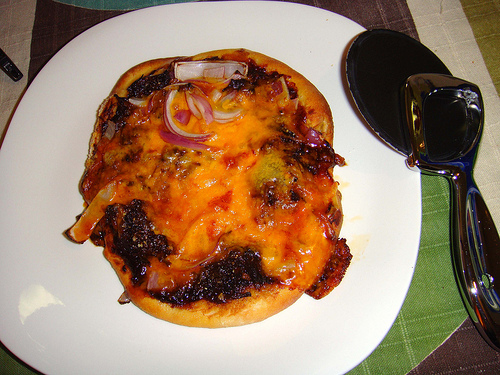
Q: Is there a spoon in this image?
A: Yes, there is a spoon.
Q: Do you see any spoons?
A: Yes, there is a spoon.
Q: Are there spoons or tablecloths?
A: Yes, there is a spoon.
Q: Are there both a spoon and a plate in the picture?
A: Yes, there are both a spoon and a plate.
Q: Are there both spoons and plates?
A: Yes, there are both a spoon and a plate.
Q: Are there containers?
A: No, there are no containers.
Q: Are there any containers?
A: No, there are no containers.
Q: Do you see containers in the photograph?
A: No, there are no containers.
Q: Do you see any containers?
A: No, there are no containers.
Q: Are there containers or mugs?
A: No, there are no containers or mugs.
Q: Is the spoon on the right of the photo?
A: Yes, the spoon is on the right of the image.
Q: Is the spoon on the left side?
A: No, the spoon is on the right of the image.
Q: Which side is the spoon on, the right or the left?
A: The spoon is on the right of the image.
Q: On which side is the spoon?
A: The spoon is on the right of the image.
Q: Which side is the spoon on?
A: The spoon is on the right of the image.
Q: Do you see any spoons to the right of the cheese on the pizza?
A: Yes, there is a spoon to the right of the cheese.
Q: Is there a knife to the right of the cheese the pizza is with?
A: No, there is a spoon to the right of the cheese.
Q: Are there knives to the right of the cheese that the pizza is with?
A: No, there is a spoon to the right of the cheese.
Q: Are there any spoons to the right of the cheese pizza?
A: Yes, there is a spoon to the right of the pizza.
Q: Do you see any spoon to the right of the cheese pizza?
A: Yes, there is a spoon to the right of the pizza.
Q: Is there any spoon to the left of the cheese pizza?
A: No, the spoon is to the right of the pizza.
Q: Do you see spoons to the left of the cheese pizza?
A: No, the spoon is to the right of the pizza.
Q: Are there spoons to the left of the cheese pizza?
A: No, the spoon is to the right of the pizza.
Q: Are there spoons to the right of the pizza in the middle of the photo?
A: Yes, there is a spoon to the right of the pizza.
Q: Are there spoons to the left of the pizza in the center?
A: No, the spoon is to the right of the pizza.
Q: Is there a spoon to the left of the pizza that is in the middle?
A: No, the spoon is to the right of the pizza.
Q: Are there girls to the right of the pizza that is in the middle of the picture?
A: No, there is a spoon to the right of the pizza.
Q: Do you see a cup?
A: No, there are no cups.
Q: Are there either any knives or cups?
A: No, there are no cups or knives.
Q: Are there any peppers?
A: No, there are no peppers.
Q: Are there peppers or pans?
A: No, there are no peppers or pans.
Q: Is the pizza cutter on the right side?
A: Yes, the pizza cutter is on the right of the image.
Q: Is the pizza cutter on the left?
A: No, the pizza cutter is on the right of the image.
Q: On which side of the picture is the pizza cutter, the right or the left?
A: The pizza cutter is on the right of the image.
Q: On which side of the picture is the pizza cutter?
A: The pizza cutter is on the right of the image.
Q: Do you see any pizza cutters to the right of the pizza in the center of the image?
A: Yes, there is a pizza cutter to the right of the pizza.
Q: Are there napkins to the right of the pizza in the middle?
A: No, there is a pizza cutter to the right of the pizza.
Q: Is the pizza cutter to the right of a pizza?
A: Yes, the pizza cutter is to the right of a pizza.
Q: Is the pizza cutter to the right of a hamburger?
A: No, the pizza cutter is to the right of a pizza.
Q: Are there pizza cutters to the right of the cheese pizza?
A: Yes, there is a pizza cutter to the right of the pizza.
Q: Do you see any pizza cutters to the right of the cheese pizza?
A: Yes, there is a pizza cutter to the right of the pizza.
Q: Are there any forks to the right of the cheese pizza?
A: No, there is a pizza cutter to the right of the pizza.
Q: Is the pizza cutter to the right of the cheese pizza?
A: Yes, the pizza cutter is to the right of the pizza.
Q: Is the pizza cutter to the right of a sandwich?
A: No, the pizza cutter is to the right of the pizza.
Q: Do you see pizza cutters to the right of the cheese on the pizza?
A: Yes, there is a pizza cutter to the right of the cheese.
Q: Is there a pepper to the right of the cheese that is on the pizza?
A: No, there is a pizza cutter to the right of the cheese.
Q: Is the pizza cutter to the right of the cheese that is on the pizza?
A: Yes, the pizza cutter is to the right of the cheese.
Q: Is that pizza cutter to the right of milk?
A: No, the pizza cutter is to the right of the cheese.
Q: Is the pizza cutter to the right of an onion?
A: Yes, the pizza cutter is to the right of an onion.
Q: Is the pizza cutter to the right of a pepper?
A: No, the pizza cutter is to the right of an onion.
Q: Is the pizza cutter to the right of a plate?
A: Yes, the pizza cutter is to the right of a plate.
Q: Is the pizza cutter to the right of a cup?
A: No, the pizza cutter is to the right of a plate.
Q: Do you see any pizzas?
A: Yes, there is a pizza.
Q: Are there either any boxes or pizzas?
A: Yes, there is a pizza.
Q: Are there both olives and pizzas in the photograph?
A: No, there is a pizza but no olives.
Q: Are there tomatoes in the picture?
A: No, there are no tomatoes.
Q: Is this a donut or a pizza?
A: This is a pizza.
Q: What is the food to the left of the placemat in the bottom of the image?
A: The food is a pizza.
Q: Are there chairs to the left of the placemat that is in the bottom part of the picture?
A: No, there is a pizza to the left of the placemat.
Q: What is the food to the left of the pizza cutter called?
A: The food is a pizza.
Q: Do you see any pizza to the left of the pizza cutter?
A: Yes, there is a pizza to the left of the pizza cutter.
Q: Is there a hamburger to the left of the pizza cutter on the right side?
A: No, there is a pizza to the left of the pizza cutter.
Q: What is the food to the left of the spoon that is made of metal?
A: The food is a pizza.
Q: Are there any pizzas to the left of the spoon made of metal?
A: Yes, there is a pizza to the left of the spoon.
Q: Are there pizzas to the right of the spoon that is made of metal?
A: No, the pizza is to the left of the spoon.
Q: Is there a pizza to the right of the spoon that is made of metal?
A: No, the pizza is to the left of the spoon.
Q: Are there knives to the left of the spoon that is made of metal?
A: No, there is a pizza to the left of the spoon.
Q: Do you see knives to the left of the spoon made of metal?
A: No, there is a pizza to the left of the spoon.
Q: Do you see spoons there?
A: Yes, there is a spoon.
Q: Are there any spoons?
A: Yes, there is a spoon.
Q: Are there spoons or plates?
A: Yes, there is a spoon.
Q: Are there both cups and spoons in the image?
A: No, there is a spoon but no cups.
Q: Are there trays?
A: No, there are no trays.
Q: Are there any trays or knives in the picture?
A: No, there are no trays or knives.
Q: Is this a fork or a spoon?
A: This is a spoon.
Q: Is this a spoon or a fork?
A: This is a spoon.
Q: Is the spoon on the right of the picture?
A: Yes, the spoon is on the right of the image.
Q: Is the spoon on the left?
A: No, the spoon is on the right of the image.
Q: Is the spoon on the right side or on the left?
A: The spoon is on the right of the image.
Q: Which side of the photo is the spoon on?
A: The spoon is on the right of the image.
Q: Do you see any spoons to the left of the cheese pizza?
A: No, the spoon is to the right of the pizza.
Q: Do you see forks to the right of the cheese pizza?
A: No, there is a spoon to the right of the pizza.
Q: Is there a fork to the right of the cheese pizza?
A: No, there is a spoon to the right of the pizza.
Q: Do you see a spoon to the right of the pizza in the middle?
A: Yes, there is a spoon to the right of the pizza.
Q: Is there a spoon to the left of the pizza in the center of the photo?
A: No, the spoon is to the right of the pizza.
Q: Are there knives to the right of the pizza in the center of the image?
A: No, there is a spoon to the right of the pizza.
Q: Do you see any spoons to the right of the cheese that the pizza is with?
A: Yes, there is a spoon to the right of the cheese.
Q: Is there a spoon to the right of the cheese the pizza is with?
A: Yes, there is a spoon to the right of the cheese.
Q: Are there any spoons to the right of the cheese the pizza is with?
A: Yes, there is a spoon to the right of the cheese.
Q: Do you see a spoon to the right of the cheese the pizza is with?
A: Yes, there is a spoon to the right of the cheese.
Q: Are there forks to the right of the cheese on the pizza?
A: No, there is a spoon to the right of the cheese.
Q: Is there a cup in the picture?
A: No, there are no cups.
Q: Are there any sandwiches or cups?
A: No, there are no cups or sandwiches.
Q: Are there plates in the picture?
A: Yes, there is a plate.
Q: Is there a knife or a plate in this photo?
A: Yes, there is a plate.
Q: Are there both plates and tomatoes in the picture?
A: No, there is a plate but no tomatoes.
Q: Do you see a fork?
A: No, there are no forks.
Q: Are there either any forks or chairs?
A: No, there are no forks or chairs.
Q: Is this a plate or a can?
A: This is a plate.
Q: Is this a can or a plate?
A: This is a plate.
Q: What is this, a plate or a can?
A: This is a plate.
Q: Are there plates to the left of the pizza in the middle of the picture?
A: Yes, there is a plate to the left of the pizza.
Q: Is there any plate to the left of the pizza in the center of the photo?
A: Yes, there is a plate to the left of the pizza.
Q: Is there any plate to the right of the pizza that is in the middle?
A: No, the plate is to the left of the pizza.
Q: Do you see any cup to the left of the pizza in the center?
A: No, there is a plate to the left of the pizza.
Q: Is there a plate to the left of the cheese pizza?
A: Yes, there is a plate to the left of the pizza.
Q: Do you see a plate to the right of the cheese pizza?
A: No, the plate is to the left of the pizza.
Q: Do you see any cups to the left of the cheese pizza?
A: No, there is a plate to the left of the pizza.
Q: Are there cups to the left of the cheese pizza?
A: No, there is a plate to the left of the pizza.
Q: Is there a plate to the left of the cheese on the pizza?
A: Yes, there is a plate to the left of the cheese.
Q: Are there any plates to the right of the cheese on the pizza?
A: No, the plate is to the left of the cheese.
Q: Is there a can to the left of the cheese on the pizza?
A: No, there is a plate to the left of the cheese.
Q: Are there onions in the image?
A: Yes, there is an onion.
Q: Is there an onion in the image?
A: Yes, there is an onion.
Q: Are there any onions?
A: Yes, there is an onion.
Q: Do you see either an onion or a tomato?
A: Yes, there is an onion.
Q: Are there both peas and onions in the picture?
A: No, there is an onion but no peas.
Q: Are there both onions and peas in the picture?
A: No, there is an onion but no peas.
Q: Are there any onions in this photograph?
A: Yes, there is an onion.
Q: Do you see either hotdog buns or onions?
A: Yes, there is an onion.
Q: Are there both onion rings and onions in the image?
A: No, there is an onion but no onion rings.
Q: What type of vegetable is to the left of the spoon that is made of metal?
A: The vegetable is an onion.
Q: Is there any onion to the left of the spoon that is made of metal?
A: Yes, there is an onion to the left of the spoon.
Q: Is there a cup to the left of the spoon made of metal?
A: No, there is an onion to the left of the spoon.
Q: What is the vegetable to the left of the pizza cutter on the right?
A: The vegetable is an onion.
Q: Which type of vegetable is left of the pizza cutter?
A: The vegetable is an onion.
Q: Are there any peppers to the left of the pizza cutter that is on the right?
A: No, there is an onion to the left of the pizza cutter.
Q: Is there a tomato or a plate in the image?
A: Yes, there is a plate.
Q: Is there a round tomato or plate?
A: Yes, there is a round plate.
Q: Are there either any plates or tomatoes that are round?
A: Yes, the plate is round.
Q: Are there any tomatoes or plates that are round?
A: Yes, the plate is round.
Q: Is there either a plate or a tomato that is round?
A: Yes, the plate is round.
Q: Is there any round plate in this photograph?
A: Yes, there is a round plate.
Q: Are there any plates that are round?
A: Yes, there is a plate that is round.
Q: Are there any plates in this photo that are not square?
A: Yes, there is a round plate.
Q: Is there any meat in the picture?
A: No, there is no meat.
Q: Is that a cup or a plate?
A: That is a plate.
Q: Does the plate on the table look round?
A: Yes, the plate is round.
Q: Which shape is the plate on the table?
A: The plate is round.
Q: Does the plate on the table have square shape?
A: No, the plate is round.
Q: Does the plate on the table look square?
A: No, the plate is round.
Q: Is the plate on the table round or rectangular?
A: The plate is round.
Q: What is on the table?
A: The plate is on the table.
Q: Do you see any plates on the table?
A: Yes, there is a plate on the table.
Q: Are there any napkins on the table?
A: No, there is a plate on the table.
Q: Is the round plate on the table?
A: Yes, the plate is on the table.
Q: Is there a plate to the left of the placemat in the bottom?
A: Yes, there is a plate to the left of the placemat.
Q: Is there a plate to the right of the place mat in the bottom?
A: No, the plate is to the left of the place mat.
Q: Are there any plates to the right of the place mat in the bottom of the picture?
A: No, the plate is to the left of the place mat.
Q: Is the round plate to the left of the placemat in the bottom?
A: Yes, the plate is to the left of the placemat.